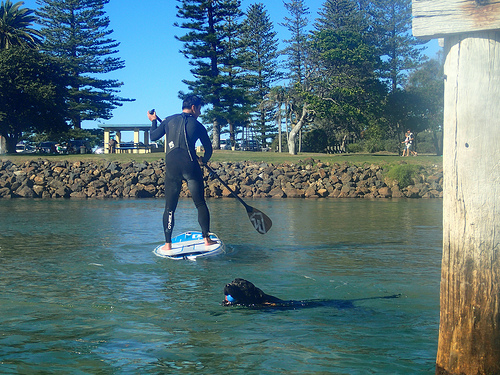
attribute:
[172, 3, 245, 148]
tree — green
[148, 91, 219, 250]
man — barefoot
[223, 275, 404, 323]
dog — black, swimming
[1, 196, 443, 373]
water — blue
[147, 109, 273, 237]
paddle — black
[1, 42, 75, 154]
tree — green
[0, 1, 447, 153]
sky — blue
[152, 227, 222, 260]
surfboard — blue, white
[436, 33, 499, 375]
pole — wooden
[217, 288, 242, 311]
mouth — open